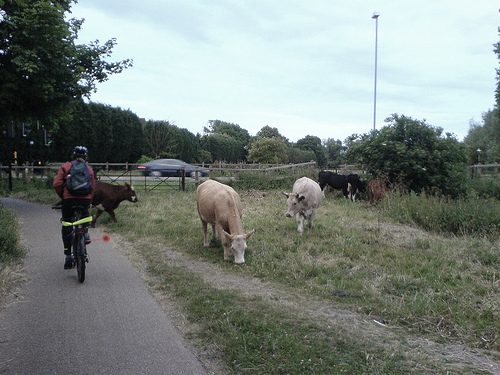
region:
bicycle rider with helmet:
[47, 139, 103, 286]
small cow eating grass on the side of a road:
[183, 176, 257, 273]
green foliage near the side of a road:
[353, 113, 491, 233]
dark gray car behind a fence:
[130, 154, 207, 183]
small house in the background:
[460, 153, 496, 183]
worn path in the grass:
[203, 256, 405, 366]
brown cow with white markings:
[91, 168, 143, 237]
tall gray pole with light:
[363, 4, 389, 144]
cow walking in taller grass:
[273, 169, 344, 246]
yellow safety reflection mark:
[53, 213, 100, 231]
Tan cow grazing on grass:
[194, 175, 256, 266]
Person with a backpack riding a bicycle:
[52, 144, 96, 285]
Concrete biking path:
[0, 195, 210, 373]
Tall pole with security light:
[366, 8, 381, 140]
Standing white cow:
[282, 175, 325, 234]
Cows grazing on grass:
[193, 168, 392, 268]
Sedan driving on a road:
[134, 156, 212, 178]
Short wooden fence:
[0, 158, 317, 185]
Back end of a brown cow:
[365, 178, 390, 208]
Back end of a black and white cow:
[342, 168, 364, 202]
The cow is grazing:
[179, 176, 278, 272]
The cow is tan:
[187, 171, 259, 275]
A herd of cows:
[96, 161, 390, 256]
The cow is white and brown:
[98, 172, 153, 236]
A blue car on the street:
[132, 154, 218, 188]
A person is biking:
[42, 133, 120, 299]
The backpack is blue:
[62, 154, 99, 196]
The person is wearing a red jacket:
[48, 144, 103, 213]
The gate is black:
[60, 159, 200, 190]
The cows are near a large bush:
[314, 112, 475, 206]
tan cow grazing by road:
[188, 178, 260, 270]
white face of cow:
[227, 235, 257, 265]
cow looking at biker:
[274, 177, 332, 234]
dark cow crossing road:
[57, 180, 137, 227]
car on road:
[140, 155, 205, 182]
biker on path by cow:
[52, 140, 112, 283]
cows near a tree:
[320, 163, 403, 198]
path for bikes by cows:
[1, 191, 215, 370]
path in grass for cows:
[148, 226, 471, 373]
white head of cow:
[280, 191, 313, 216]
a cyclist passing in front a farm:
[52, 135, 105, 282]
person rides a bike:
[43, 140, 101, 280]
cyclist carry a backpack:
[52, 140, 102, 206]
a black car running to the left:
[131, 150, 211, 180]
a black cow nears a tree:
[315, 160, 370, 200]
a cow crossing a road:
[91, 172, 137, 227]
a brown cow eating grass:
[186, 170, 256, 270]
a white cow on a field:
[276, 165, 331, 235]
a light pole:
[363, 0, 384, 131]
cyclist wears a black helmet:
[54, 138, 99, 186]